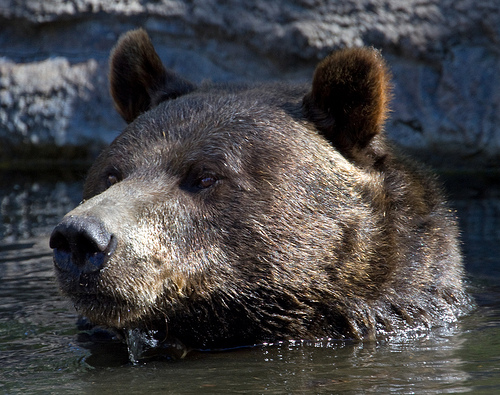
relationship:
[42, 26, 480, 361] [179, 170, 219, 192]
bear has eye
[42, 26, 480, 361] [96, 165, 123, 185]
bear has eye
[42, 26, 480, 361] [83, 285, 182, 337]
bear has mouth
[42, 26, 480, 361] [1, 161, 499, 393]
bear in water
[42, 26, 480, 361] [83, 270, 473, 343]
bear has fur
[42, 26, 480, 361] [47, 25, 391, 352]
bear has head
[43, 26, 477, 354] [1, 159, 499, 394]
bear swimming near river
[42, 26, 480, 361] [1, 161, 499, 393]
bear near water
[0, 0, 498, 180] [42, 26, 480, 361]
wall near bear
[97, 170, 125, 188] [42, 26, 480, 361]
eye of bear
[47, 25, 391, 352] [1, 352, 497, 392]
head sticking out of water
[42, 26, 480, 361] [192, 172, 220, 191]
bear has eye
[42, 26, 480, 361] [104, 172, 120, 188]
bear has eye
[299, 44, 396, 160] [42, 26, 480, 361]
ear of bear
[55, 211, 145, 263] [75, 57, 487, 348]
nose of bear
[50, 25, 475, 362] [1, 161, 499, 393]
bear's head popping out of water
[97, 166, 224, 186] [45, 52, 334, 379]
eyes of bear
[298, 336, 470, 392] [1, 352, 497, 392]
reflection in water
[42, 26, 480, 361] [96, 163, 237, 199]
bear has eyes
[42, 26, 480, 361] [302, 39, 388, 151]
bear has ears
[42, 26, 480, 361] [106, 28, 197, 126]
bear has ears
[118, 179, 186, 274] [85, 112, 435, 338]
sun reflecting off bear